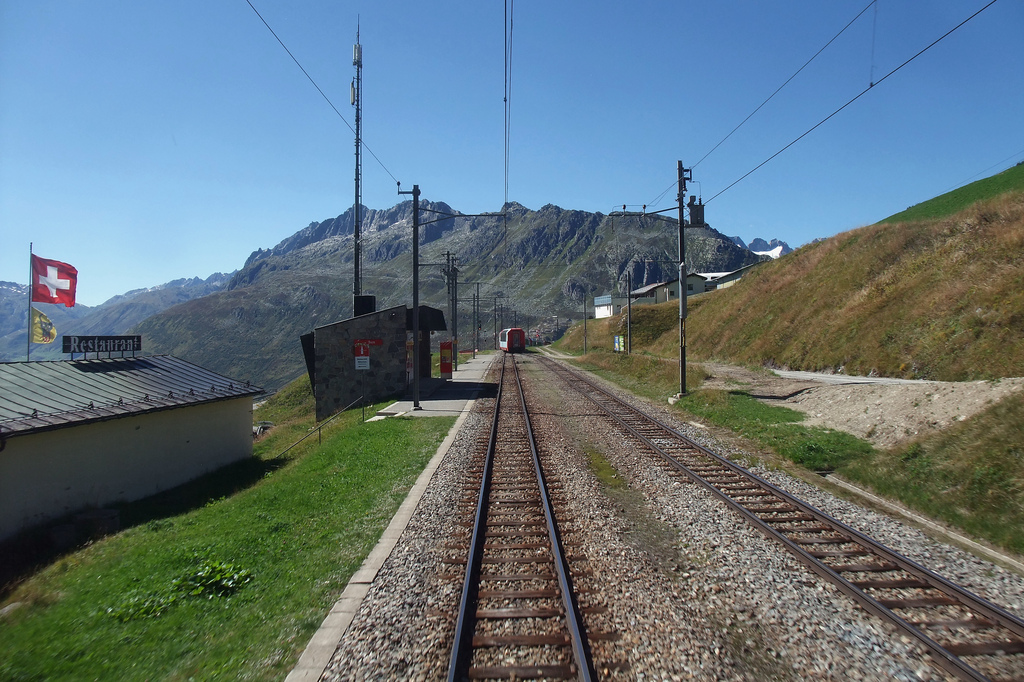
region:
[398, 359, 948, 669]
rails on the ground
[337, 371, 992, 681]
gravel around the rails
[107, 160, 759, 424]
the mountain is not too high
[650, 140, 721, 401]
the pole holding wires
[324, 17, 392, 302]
the pole holds wires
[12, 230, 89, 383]
the flag is red and white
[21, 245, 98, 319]
the crooss is white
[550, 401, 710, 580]
grass growing among the gravel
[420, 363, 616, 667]
wood planks below the rail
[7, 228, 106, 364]
Flag is on a building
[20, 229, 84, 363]
Swiss flag on a building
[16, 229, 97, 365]
Swiss flag is on a building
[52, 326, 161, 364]
Sign on a building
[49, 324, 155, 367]
Sign is on a building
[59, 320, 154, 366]
Sign on top of a building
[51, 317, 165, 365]
Sign is on top of a building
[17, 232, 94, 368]
Flag on top of a building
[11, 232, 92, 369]
Flag is on top of a building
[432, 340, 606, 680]
train tracks on ground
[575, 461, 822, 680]
gravel on train tracks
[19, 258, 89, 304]
red and white flag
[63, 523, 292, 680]
green grass on ground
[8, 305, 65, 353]
yellow flag flying in air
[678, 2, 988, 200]
power lines in air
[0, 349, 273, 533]
building next to train tracks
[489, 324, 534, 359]
train on the tracks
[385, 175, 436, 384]
light pole in ground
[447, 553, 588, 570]
railroad track has a wood plank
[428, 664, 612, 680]
railroad track has a wood plank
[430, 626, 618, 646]
railroad track has a wood plank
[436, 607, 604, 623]
railroad track has a wood plank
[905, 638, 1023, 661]
railroad track has a wood plank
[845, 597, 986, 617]
railroad track has a wood plank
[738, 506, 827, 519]
railroad track has a wood plank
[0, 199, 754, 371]
large mountains in the background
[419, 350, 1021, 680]
two sets of train tracks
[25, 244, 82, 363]
flags on top of the building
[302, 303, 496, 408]
waiting area beside the tracks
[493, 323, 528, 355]
train far back on the tracks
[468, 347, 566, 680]
it is brown train tracks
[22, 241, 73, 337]
it is a red flag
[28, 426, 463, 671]
a area of green grass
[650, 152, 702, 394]
it is a tall skinny pole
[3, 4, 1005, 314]
the sky is blue and clear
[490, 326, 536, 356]
a red and white train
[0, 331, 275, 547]
a small white building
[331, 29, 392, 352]
a tall pole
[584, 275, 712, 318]
a white building